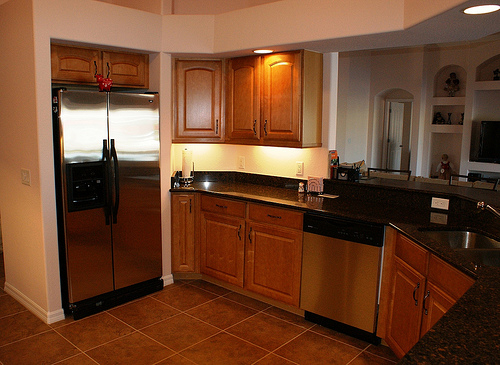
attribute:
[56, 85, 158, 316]
refrigerator — stainless steel, here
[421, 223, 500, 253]
sink — double, kitchen's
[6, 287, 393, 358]
floor — tiled, kitchen's, covered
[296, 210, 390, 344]
dishwasher — brown, black, electric, stainless steel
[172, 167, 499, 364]
counter — kitchen's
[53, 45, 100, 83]
cabinet — small, brown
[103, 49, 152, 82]
cabinet — small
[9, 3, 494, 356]
scene — kitchen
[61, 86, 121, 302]
freezer — here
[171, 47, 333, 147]
cabinets — overhead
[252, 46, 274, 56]
light — round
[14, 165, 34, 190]
light switch — here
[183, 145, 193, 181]
roll — paper, towels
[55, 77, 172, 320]
doors — stainless steel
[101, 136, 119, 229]
handles — black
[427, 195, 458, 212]
socket — electrical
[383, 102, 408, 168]
door — open, white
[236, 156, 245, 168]
outlet — white